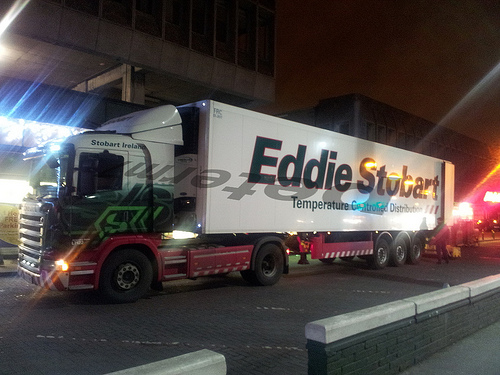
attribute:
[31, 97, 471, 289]
truck — big, white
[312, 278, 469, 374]
wall — brick, retainer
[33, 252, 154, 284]
lights — red, shining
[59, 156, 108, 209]
mirror — black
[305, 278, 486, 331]
wall edge — grey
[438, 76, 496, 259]
lights — blurry, bright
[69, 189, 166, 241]
logo — green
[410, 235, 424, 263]
wheel — black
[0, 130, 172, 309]
cab — green, red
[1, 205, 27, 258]
sign — yellow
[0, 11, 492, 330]
photo — dark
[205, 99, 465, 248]
trailer — white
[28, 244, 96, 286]
lights — on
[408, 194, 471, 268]
man — standing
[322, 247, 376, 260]
stripes — white